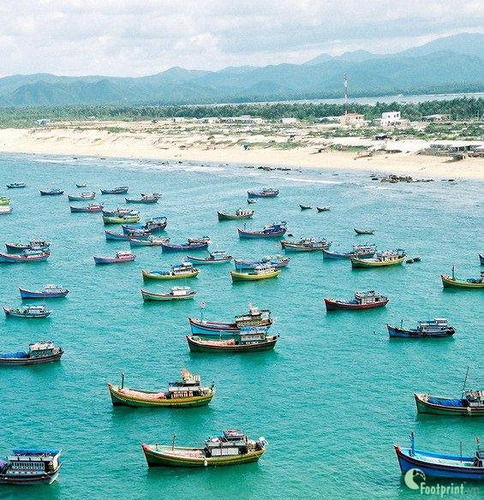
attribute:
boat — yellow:
[105, 373, 217, 411]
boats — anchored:
[184, 298, 282, 359]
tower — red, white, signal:
[330, 70, 370, 131]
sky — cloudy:
[0, 0, 481, 71]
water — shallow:
[2, 152, 479, 495]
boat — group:
[101, 366, 215, 410]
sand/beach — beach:
[1, 119, 477, 158]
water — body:
[272, 309, 324, 369]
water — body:
[138, 91, 483, 108]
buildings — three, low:
[344, 104, 459, 134]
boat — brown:
[213, 201, 262, 229]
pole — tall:
[340, 66, 354, 108]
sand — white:
[221, 143, 330, 166]